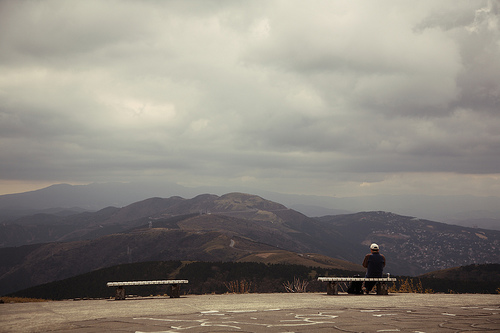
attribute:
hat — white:
[370, 242, 379, 251]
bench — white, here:
[108, 279, 190, 289]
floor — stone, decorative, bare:
[2, 294, 499, 332]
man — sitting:
[363, 244, 387, 295]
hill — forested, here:
[4, 260, 499, 302]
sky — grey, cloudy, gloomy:
[2, 0, 499, 232]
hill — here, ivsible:
[4, 212, 499, 294]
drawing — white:
[134, 308, 463, 330]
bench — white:
[319, 276, 399, 284]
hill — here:
[1, 190, 312, 244]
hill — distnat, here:
[1, 183, 499, 230]